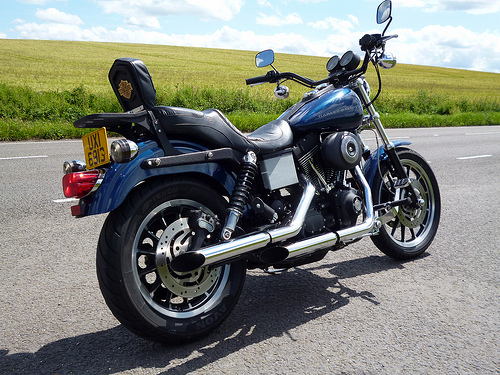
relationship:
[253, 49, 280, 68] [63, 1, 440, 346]
mirror on bike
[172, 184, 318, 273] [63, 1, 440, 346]
pipe on bike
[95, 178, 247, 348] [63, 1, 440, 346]
wheel on bike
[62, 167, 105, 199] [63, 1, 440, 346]
light on bike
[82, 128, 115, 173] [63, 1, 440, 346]
plate on bike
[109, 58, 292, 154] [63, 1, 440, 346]
seat of bike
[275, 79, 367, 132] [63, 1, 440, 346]
tank on bike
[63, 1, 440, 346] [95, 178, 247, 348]
bike has wheel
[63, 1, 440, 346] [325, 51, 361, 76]
bike has gauges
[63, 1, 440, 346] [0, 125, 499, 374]
bike on road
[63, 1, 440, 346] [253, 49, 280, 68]
bike has mirror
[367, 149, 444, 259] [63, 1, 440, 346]
tire on bike